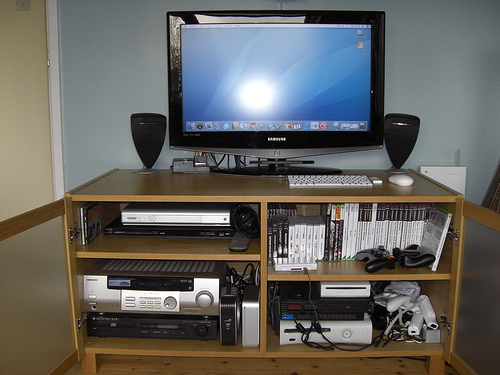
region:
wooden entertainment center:
[66, 168, 462, 369]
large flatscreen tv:
[165, 6, 380, 176]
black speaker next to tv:
[125, 111, 165, 171]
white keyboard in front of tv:
[285, 171, 367, 186]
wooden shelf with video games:
[265, 257, 445, 278]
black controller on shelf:
[352, 245, 392, 270]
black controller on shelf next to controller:
[395, 240, 430, 265]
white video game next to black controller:
[420, 205, 450, 270]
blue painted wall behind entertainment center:
[60, 0, 496, 205]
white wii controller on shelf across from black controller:
[270, 258, 320, 271]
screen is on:
[205, 33, 416, 143]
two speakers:
[121, 97, 458, 157]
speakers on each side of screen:
[111, 113, 465, 162]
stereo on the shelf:
[96, 271, 250, 326]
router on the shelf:
[223, 279, 266, 355]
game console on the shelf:
[275, 308, 398, 368]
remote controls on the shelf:
[375, 272, 483, 349]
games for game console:
[260, 199, 447, 268]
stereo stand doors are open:
[2, 201, 497, 368]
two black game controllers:
[367, 233, 434, 264]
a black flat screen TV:
[157, 8, 389, 164]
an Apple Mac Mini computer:
[237, 299, 262, 351]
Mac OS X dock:
[185, 119, 365, 136]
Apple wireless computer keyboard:
[278, 169, 373, 189]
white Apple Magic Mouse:
[386, 170, 412, 185]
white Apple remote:
[366, 172, 381, 184]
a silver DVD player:
[112, 207, 230, 229]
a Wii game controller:
[410, 293, 445, 334]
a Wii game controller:
[406, 300, 430, 339]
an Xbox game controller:
[352, 243, 395, 275]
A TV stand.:
[61, 163, 470, 372]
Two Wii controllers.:
[404, 298, 439, 341]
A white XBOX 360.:
[279, 318, 375, 349]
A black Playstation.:
[276, 291, 373, 321]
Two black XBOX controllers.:
[353, 242, 437, 273]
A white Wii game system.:
[314, 278, 377, 298]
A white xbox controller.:
[371, 285, 411, 312]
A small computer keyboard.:
[276, 167, 375, 197]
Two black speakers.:
[126, 107, 422, 170]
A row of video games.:
[268, 204, 443, 269]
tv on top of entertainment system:
[157, 5, 398, 168]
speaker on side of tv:
[374, 109, 421, 173]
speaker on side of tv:
[126, 108, 166, 173]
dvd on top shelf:
[340, 205, 348, 260]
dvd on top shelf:
[345, 204, 352, 261]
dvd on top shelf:
[429, 211, 446, 273]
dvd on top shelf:
[400, 203, 407, 243]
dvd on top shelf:
[387, 206, 397, 250]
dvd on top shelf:
[377, 207, 385, 247]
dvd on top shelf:
[403, 207, 410, 245]